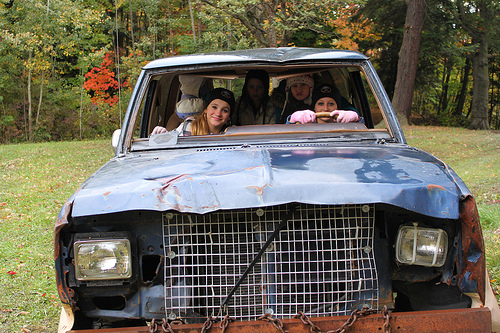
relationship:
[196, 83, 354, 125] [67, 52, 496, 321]
people sitting in car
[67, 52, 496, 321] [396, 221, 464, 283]
car has headlight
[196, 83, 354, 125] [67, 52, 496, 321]
people in car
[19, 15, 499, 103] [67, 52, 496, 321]
trees behind car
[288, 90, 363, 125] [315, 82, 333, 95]
girl wearing cap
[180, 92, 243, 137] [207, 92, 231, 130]
woman has head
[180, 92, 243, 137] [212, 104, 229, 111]
woman has eye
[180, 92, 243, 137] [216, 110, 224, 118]
woman has nose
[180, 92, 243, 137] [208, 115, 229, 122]
woman has mouth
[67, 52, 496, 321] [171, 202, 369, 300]
car has grill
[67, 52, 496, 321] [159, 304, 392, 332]
car has chain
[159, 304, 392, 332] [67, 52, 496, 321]
chain in front of car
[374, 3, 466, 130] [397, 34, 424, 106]
tree has trunk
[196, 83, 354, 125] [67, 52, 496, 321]
people inside car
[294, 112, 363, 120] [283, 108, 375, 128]
hands on steering wheel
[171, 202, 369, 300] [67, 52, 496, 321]
grill in front of car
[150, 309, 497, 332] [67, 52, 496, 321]
bumper in front of car